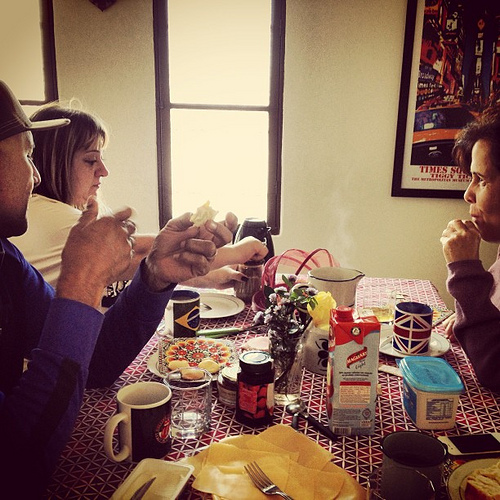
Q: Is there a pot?
A: No, there are no pots.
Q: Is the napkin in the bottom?
A: Yes, the napkin is in the bottom of the image.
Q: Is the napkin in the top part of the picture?
A: No, the napkin is in the bottom of the image.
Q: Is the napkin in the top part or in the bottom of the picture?
A: The napkin is in the bottom of the image.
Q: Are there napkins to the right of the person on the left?
A: Yes, there is a napkin to the right of the person.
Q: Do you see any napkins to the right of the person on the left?
A: Yes, there is a napkin to the right of the person.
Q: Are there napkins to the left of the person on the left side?
A: No, the napkin is to the right of the person.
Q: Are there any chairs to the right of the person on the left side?
A: No, there is a napkin to the right of the person.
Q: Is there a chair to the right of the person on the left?
A: No, there is a napkin to the right of the person.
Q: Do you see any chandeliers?
A: No, there are no chandeliers.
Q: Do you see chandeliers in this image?
A: No, there are no chandeliers.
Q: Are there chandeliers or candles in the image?
A: No, there are no chandeliers or candles.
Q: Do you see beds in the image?
A: No, there are no beds.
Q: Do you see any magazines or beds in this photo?
A: No, there are no beds or magazines.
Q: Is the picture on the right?
A: Yes, the picture is on the right of the image.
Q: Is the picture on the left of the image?
A: No, the picture is on the right of the image.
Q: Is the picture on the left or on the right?
A: The picture is on the right of the image.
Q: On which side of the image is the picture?
A: The picture is on the right of the image.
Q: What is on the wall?
A: The picture is on the wall.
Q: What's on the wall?
A: The picture is on the wall.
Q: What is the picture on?
A: The picture is on the wall.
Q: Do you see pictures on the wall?
A: Yes, there is a picture on the wall.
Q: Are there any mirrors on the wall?
A: No, there is a picture on the wall.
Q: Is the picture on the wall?
A: Yes, the picture is on the wall.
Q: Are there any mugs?
A: Yes, there is a mug.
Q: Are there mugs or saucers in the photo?
A: Yes, there is a mug.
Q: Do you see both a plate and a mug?
A: Yes, there are both a mug and a plate.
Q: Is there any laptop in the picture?
A: No, there are no laptops.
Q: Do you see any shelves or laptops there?
A: No, there are no laptops or shelves.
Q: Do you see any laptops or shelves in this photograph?
A: No, there are no laptops or shelves.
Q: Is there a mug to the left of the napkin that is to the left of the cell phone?
A: Yes, there is a mug to the left of the napkin.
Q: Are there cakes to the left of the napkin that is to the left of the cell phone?
A: No, there is a mug to the left of the napkin.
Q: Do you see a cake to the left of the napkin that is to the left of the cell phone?
A: No, there is a mug to the left of the napkin.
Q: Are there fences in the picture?
A: No, there are no fences.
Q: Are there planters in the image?
A: No, there are no planters.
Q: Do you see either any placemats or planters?
A: No, there are no planters or placemats.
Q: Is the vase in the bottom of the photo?
A: Yes, the vase is in the bottom of the image.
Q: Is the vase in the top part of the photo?
A: No, the vase is in the bottom of the image.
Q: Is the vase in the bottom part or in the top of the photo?
A: The vase is in the bottom of the image.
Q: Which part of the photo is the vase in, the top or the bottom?
A: The vase is in the bottom of the image.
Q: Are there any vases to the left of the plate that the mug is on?
A: Yes, there is a vase to the left of the plate.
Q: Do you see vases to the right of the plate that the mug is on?
A: No, the vase is to the left of the plate.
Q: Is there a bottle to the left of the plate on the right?
A: No, there is a vase to the left of the plate.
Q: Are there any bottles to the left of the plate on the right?
A: No, there is a vase to the left of the plate.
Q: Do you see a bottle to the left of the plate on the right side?
A: No, there is a vase to the left of the plate.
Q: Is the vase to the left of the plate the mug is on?
A: Yes, the vase is to the left of the plate.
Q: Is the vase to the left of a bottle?
A: No, the vase is to the left of the plate.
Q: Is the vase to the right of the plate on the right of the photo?
A: No, the vase is to the left of the plate.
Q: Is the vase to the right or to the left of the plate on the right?
A: The vase is to the left of the plate.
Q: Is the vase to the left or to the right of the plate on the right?
A: The vase is to the left of the plate.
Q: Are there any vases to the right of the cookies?
A: Yes, there is a vase to the right of the cookies.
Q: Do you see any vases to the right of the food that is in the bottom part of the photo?
A: Yes, there is a vase to the right of the cookies.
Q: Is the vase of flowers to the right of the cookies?
A: Yes, the vase is to the right of the cookies.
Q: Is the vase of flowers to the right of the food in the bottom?
A: Yes, the vase is to the right of the cookies.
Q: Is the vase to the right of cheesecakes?
A: No, the vase is to the right of the cookies.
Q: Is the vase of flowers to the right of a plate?
A: Yes, the vase is to the right of a plate.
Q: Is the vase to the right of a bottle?
A: No, the vase is to the right of a plate.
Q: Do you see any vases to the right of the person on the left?
A: Yes, there is a vase to the right of the person.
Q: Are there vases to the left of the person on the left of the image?
A: No, the vase is to the right of the person.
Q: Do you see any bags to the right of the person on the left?
A: No, there is a vase to the right of the person.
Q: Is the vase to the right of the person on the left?
A: Yes, the vase is to the right of the person.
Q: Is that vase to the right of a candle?
A: No, the vase is to the right of the person.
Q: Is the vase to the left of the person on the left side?
A: No, the vase is to the right of the person.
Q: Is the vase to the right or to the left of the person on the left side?
A: The vase is to the right of the person.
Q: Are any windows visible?
A: Yes, there is a window.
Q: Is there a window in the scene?
A: Yes, there is a window.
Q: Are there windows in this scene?
A: Yes, there is a window.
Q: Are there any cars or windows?
A: Yes, there is a window.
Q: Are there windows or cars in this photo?
A: Yes, there is a window.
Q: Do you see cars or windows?
A: Yes, there is a window.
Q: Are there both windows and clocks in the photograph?
A: No, there is a window but no clocks.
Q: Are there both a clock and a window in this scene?
A: No, there is a window but no clocks.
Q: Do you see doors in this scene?
A: No, there are no doors.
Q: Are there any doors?
A: No, there are no doors.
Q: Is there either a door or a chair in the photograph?
A: No, there are no doors or chairs.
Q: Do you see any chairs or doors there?
A: No, there are no doors or chairs.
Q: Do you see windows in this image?
A: Yes, there is a window.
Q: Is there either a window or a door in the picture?
A: Yes, there is a window.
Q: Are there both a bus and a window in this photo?
A: No, there is a window but no buses.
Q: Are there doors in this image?
A: No, there are no doors.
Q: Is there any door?
A: No, there are no doors.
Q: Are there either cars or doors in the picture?
A: No, there are no doors or cars.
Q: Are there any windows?
A: Yes, there is a window.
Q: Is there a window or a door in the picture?
A: Yes, there is a window.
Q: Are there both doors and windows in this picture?
A: No, there is a window but no doors.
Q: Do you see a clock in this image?
A: No, there are no clocks.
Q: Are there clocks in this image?
A: No, there are no clocks.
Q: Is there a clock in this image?
A: No, there are no clocks.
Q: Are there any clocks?
A: No, there are no clocks.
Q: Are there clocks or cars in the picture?
A: No, there are no clocks or cars.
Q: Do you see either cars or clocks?
A: No, there are no clocks or cars.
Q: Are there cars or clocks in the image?
A: No, there are no clocks or cars.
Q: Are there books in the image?
A: No, there are no books.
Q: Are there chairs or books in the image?
A: No, there are no books or chairs.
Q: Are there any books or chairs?
A: No, there are no books or chairs.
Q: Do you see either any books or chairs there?
A: No, there are no books or chairs.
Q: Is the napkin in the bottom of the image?
A: Yes, the napkin is in the bottom of the image.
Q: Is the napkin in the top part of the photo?
A: No, the napkin is in the bottom of the image.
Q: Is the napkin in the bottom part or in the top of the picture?
A: The napkin is in the bottom of the image.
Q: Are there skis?
A: No, there are no skis.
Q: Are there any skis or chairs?
A: No, there are no skis or chairs.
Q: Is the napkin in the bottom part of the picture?
A: Yes, the napkin is in the bottom of the image.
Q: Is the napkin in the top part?
A: No, the napkin is in the bottom of the image.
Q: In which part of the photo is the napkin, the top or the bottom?
A: The napkin is in the bottom of the image.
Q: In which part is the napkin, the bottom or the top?
A: The napkin is in the bottom of the image.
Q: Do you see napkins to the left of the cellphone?
A: Yes, there is a napkin to the left of the cellphone.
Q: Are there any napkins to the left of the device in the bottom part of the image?
A: Yes, there is a napkin to the left of the cellphone.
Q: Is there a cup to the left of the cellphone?
A: No, there is a napkin to the left of the cellphone.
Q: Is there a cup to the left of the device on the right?
A: No, there is a napkin to the left of the cellphone.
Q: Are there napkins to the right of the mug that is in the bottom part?
A: Yes, there is a napkin to the right of the mug.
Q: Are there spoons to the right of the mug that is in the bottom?
A: No, there is a napkin to the right of the mug.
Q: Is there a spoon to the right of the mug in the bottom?
A: No, there is a napkin to the right of the mug.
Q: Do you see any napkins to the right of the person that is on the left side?
A: Yes, there is a napkin to the right of the person.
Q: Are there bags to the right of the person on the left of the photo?
A: No, there is a napkin to the right of the person.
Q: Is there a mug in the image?
A: Yes, there is a mug.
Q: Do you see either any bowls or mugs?
A: Yes, there is a mug.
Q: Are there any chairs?
A: No, there are no chairs.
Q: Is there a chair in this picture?
A: No, there are no chairs.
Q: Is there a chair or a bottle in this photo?
A: No, there are no chairs or bottles.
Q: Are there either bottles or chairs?
A: No, there are no chairs or bottles.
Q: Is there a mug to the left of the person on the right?
A: Yes, there is a mug to the left of the person.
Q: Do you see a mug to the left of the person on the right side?
A: Yes, there is a mug to the left of the person.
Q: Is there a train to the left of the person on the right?
A: No, there is a mug to the left of the person.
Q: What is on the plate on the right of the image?
A: The mug is on the plate.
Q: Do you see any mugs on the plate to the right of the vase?
A: Yes, there is a mug on the plate.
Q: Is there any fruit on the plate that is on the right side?
A: No, there is a mug on the plate.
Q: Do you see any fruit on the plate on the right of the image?
A: No, there is a mug on the plate.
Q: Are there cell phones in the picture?
A: Yes, there is a cell phone.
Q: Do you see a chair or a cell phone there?
A: Yes, there is a cell phone.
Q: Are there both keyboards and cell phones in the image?
A: No, there is a cell phone but no keyboards.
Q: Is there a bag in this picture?
A: No, there are no bags.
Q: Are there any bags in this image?
A: No, there are no bags.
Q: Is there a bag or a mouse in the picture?
A: No, there are no bags or computer mice.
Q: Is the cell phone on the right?
A: Yes, the cell phone is on the right of the image.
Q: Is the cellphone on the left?
A: No, the cellphone is on the right of the image.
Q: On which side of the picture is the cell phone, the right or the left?
A: The cell phone is on the right of the image.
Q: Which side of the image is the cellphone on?
A: The cellphone is on the right of the image.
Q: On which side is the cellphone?
A: The cellphone is on the right of the image.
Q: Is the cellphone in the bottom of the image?
A: Yes, the cellphone is in the bottom of the image.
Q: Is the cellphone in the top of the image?
A: No, the cellphone is in the bottom of the image.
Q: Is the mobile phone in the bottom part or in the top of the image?
A: The mobile phone is in the bottom of the image.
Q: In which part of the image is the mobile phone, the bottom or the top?
A: The mobile phone is in the bottom of the image.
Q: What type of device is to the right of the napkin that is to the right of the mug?
A: The device is a cell phone.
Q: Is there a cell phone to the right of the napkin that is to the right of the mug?
A: Yes, there is a cell phone to the right of the napkin.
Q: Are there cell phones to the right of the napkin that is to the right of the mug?
A: Yes, there is a cell phone to the right of the napkin.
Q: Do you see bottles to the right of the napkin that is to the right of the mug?
A: No, there is a cell phone to the right of the napkin.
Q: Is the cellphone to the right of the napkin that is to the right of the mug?
A: Yes, the cellphone is to the right of the napkin.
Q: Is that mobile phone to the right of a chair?
A: No, the mobile phone is to the right of the napkin.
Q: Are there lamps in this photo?
A: No, there are no lamps.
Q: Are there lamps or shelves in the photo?
A: No, there are no lamps or shelves.